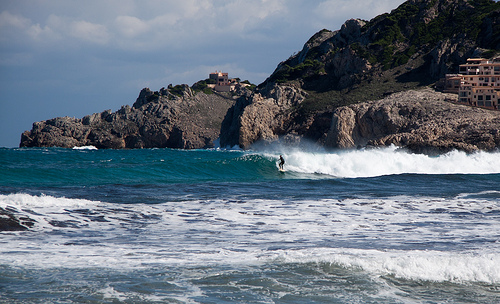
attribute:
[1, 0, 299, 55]
cloud — white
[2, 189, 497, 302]
foam — white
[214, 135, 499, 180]
foam — white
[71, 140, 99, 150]
foam — white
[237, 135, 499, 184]
wave — large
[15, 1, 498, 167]
rock — large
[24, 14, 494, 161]
cliff — rocky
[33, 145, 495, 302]
water — blue